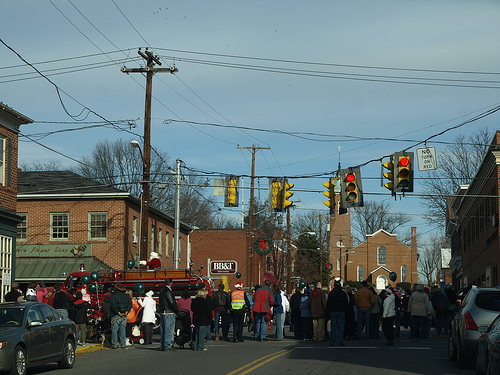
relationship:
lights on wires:
[219, 174, 244, 211] [158, 166, 499, 202]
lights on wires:
[265, 174, 294, 213] [158, 166, 499, 202]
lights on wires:
[321, 174, 343, 216] [158, 166, 499, 202]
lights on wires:
[340, 169, 365, 211] [158, 166, 499, 202]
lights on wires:
[380, 150, 418, 198] [158, 166, 499, 202]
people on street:
[19, 281, 436, 350] [21, 329, 459, 371]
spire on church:
[329, 142, 349, 178] [314, 145, 420, 288]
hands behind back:
[116, 307, 128, 318] [107, 291, 133, 314]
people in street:
[19, 281, 436, 350] [21, 329, 459, 371]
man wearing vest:
[223, 282, 248, 342] [231, 290, 247, 309]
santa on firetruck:
[138, 248, 163, 273] [55, 268, 216, 331]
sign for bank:
[207, 258, 239, 279] [205, 260, 239, 275]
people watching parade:
[19, 281, 436, 350] [13, 269, 251, 331]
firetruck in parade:
[55, 268, 216, 331] [13, 269, 251, 331]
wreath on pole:
[250, 235, 275, 256] [239, 148, 267, 316]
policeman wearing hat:
[223, 282, 248, 342] [231, 276, 242, 289]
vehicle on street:
[1, 298, 85, 375] [21, 329, 459, 371]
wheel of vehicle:
[9, 346, 31, 375] [1, 298, 85, 375]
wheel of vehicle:
[61, 337, 77, 368] [1, 298, 85, 375]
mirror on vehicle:
[25, 318, 44, 330] [1, 298, 85, 375]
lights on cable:
[392, 151, 415, 192] [158, 127, 497, 210]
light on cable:
[340, 169, 365, 211] [158, 127, 497, 210]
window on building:
[86, 208, 109, 244] [18, 166, 188, 308]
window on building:
[48, 210, 71, 243] [18, 166, 188, 308]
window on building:
[14, 212, 28, 243] [18, 166, 188, 308]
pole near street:
[239, 148, 267, 316] [21, 329, 459, 371]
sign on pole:
[207, 258, 239, 279] [239, 148, 267, 316]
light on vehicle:
[458, 307, 477, 335] [447, 281, 495, 365]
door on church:
[373, 274, 388, 296] [314, 145, 420, 288]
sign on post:
[207, 258, 239, 279] [203, 256, 216, 302]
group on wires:
[208, 147, 420, 219] [158, 166, 499, 202]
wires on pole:
[158, 166, 499, 202] [239, 148, 267, 316]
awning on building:
[17, 245, 110, 285] [18, 166, 188, 308]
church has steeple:
[314, 145, 420, 288] [321, 145, 353, 282]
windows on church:
[358, 243, 412, 279] [314, 145, 420, 288]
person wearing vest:
[223, 282, 248, 342] [231, 290, 247, 309]